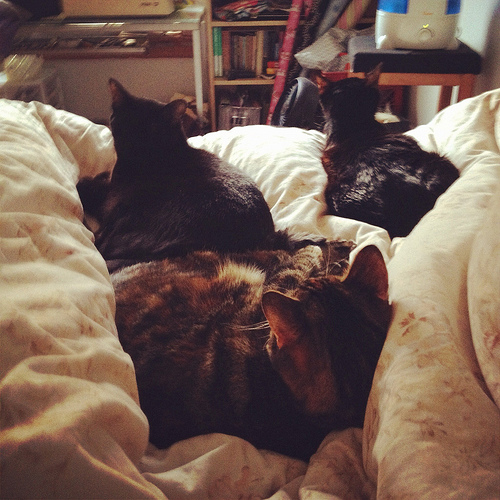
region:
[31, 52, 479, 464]
Three cats on a bed.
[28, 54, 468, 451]
Three cats in a room.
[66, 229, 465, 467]
One cat sleeping.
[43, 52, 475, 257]
Two cats watching TV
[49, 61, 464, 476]
Two black cats and one brown striped cat.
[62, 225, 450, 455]
The brown striped cat is sleeping.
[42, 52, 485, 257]
Two black cats watching TV.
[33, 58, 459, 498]
Three cats in bed together.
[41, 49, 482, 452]
Three cats resting comfortably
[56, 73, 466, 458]
Three cats.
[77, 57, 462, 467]
cats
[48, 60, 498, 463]
three cats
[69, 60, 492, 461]
three cats are on a bed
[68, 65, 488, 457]
three cats are lying on a bed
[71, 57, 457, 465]
three brown cats on a bed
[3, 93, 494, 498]
the bed has a fluffy blanket with a floral pattern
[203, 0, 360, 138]
a bookshelf against the wall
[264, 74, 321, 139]
a black fan on the floor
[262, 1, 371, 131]
wrapping paper rolls are leaning against the bookcase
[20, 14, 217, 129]
a white desk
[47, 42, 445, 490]
cats on the bed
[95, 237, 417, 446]
this cat is striped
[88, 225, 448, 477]
this cat is sleeping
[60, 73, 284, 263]
this cat is looking away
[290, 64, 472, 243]
this cat is black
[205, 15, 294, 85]
books on the bookcase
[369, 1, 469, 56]
a machine on the table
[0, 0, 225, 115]
a computer desk across the room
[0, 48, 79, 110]
plastic storage under the desk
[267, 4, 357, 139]
wrapping paper leaning on the bookcase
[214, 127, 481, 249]
the cat is black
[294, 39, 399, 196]
the cat is black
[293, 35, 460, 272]
the cat is black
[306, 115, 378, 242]
the cat is black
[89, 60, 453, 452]
three cats on a comforter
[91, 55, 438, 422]
the cats are laying down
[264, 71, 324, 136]
the fan beside the bed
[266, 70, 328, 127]
the fan is black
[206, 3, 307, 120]
the books on the book shelf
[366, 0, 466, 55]
the humidifier beside the bed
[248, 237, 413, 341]
the ears of the cat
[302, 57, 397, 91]
the ears of the cat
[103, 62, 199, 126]
the ears of the cat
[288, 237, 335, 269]
the paw of the cat